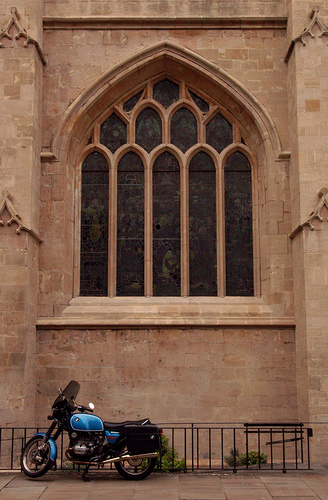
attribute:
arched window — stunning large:
[59, 44, 283, 327]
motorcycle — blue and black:
[4, 376, 178, 482]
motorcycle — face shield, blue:
[19, 378, 165, 486]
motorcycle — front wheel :
[16, 431, 63, 479]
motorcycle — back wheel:
[114, 444, 166, 482]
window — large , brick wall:
[62, 44, 286, 334]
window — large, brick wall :
[46, 35, 279, 301]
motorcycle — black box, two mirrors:
[17, 374, 169, 481]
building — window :
[45, 16, 283, 485]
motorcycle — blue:
[5, 382, 177, 498]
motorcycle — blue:
[31, 371, 193, 487]